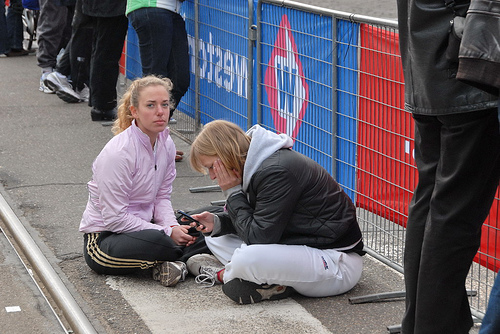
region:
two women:
[80, 75, 368, 298]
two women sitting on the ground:
[77, 80, 365, 292]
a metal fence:
[290, 47, 370, 129]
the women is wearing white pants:
[249, 246, 312, 278]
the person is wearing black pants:
[408, 117, 479, 331]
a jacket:
[85, 139, 164, 231]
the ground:
[16, 105, 77, 159]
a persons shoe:
[42, 71, 74, 101]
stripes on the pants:
[87, 251, 166, 266]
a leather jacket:
[395, 8, 467, 107]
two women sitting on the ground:
[70, 71, 377, 307]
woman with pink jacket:
[75, 70, 208, 290]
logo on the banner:
[254, 47, 317, 128]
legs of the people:
[25, 33, 121, 120]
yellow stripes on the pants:
[86, 236, 114, 267]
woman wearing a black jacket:
[185, 114, 361, 249]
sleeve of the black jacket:
[454, 54, 498, 91]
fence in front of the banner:
[342, 98, 381, 143]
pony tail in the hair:
[114, 92, 133, 134]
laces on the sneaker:
[192, 267, 222, 284]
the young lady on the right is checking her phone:
[174, 203, 213, 231]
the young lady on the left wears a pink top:
[75, 118, 184, 239]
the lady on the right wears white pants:
[201, 229, 365, 299]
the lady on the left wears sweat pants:
[80, 222, 210, 278]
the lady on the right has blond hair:
[186, 115, 258, 187]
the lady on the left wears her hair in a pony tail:
[108, 73, 173, 133]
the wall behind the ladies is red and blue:
[261, 1, 421, 221]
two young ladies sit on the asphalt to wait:
[72, 71, 369, 301]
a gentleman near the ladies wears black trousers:
[396, 99, 498, 331]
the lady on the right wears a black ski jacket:
[220, 121, 368, 255]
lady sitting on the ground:
[63, 64, 226, 289]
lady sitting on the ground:
[185, 111, 387, 309]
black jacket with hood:
[207, 121, 369, 246]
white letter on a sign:
[231, 51, 255, 102]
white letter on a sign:
[221, 45, 236, 93]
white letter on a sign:
[212, 40, 227, 89]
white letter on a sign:
[203, 28, 215, 88]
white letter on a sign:
[195, 34, 210, 80]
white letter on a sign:
[187, 32, 199, 74]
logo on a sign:
[262, 9, 312, 151]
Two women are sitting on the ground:
[76, 70, 375, 314]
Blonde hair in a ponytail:
[105, 72, 173, 135]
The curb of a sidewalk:
[1, 187, 104, 332]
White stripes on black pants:
[80, 229, 187, 278]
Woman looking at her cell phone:
[170, 116, 267, 238]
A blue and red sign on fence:
[119, 0, 498, 273]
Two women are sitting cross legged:
[75, 69, 368, 308]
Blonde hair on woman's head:
[184, 115, 253, 192]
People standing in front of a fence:
[1, 1, 195, 132]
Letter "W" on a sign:
[268, 56, 303, 120]